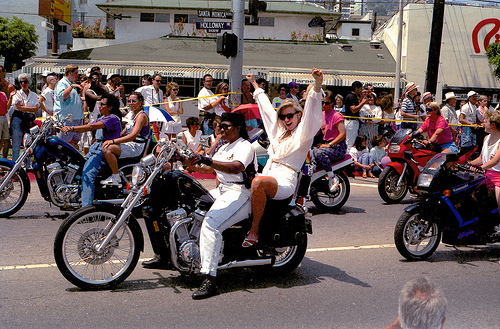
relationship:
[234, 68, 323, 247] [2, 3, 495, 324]
female in parade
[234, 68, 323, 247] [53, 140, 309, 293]
lady on motorcycle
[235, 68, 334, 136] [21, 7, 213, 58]
arms in air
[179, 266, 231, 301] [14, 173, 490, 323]
feet on ground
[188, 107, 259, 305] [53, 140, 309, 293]
driver of motorcycle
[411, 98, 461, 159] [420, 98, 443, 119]
lady wearing sunglasses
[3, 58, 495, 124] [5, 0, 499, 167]
people on roadside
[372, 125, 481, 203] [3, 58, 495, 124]
motorcycle near crowd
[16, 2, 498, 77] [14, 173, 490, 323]
shops on road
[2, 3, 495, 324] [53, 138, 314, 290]
parde of motorcycle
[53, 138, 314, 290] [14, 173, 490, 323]
motorcycle on road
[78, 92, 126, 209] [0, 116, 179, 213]
lady on motorcycle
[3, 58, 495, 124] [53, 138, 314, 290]
people watch motorcycle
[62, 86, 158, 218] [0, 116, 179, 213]
women on bike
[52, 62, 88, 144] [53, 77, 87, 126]
man in blue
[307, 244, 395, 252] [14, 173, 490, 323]
line on road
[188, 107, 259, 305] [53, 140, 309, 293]
person on motorcycle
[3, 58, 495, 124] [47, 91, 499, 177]
people on motorcycles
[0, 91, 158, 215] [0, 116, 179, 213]
women on motorcycles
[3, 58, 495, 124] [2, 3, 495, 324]
people watching parade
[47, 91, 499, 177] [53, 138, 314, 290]
people riding motorcycle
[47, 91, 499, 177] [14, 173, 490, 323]
riders in street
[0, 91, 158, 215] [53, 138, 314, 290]
women on motorcycle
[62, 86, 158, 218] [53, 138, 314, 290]
women riding motorcycle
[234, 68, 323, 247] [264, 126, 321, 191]
woman in white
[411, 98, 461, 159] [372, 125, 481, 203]
woman on motorcycle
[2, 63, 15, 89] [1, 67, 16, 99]
head of man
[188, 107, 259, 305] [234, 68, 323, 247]
man ahead woman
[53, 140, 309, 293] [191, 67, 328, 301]
motorcycle under people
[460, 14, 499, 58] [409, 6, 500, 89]
writing on wall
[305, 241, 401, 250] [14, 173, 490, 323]
line on road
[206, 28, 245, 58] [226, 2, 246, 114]
signal on pole